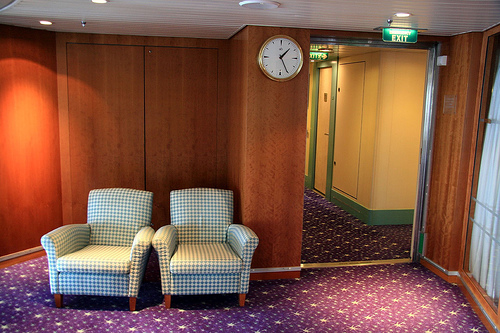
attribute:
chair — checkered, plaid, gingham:
[39, 189, 156, 311]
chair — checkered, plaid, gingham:
[151, 187, 260, 308]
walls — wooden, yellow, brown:
[0, 24, 482, 283]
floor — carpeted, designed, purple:
[0, 186, 488, 332]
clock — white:
[257, 35, 305, 83]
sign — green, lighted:
[381, 28, 417, 44]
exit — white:
[392, 35, 408, 42]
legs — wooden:
[54, 292, 135, 310]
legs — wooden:
[164, 294, 246, 308]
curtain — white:
[467, 63, 499, 300]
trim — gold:
[258, 34, 304, 82]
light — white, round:
[39, 19, 52, 26]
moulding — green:
[312, 37, 439, 265]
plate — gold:
[442, 95, 458, 112]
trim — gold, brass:
[301, 258, 413, 269]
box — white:
[436, 56, 448, 66]